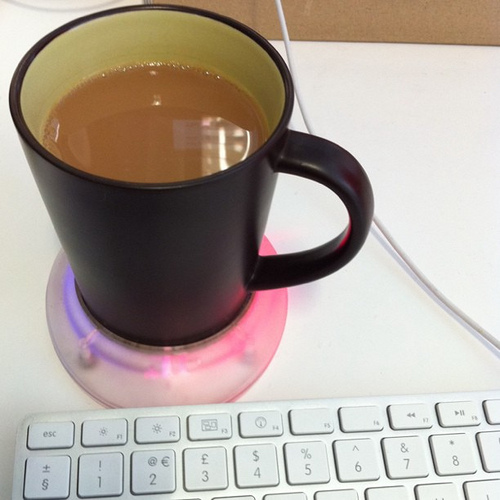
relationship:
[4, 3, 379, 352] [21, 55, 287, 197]
cup of coffee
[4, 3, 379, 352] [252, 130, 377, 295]
cup has handle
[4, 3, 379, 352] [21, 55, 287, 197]
cup filled with coffee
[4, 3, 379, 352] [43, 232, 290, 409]
cup in cupholder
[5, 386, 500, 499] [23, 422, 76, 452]
keyboard has escape key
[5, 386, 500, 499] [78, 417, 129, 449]
keyboard has f1 key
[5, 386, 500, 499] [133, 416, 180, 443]
keyboard has f2 key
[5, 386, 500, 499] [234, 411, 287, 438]
keyboard has f4 key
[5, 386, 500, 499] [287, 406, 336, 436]
keyboard has f5 key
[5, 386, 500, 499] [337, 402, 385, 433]
keyboard has f6 key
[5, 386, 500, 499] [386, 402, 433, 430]
keyboard has f7 key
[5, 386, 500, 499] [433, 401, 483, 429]
keyboard has f8 key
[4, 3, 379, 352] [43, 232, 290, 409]
cup on cupholder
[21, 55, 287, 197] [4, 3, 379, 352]
coffee inside cup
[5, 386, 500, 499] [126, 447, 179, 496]
keyboard has #2 key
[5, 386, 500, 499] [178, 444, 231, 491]
keyboard has #3 key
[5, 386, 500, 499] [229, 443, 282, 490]
keyboard has #4 key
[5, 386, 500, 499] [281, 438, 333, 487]
keyboard has #5 key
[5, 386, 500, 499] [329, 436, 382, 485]
keyboard has #6 key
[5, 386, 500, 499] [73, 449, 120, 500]
keyboard has #1 key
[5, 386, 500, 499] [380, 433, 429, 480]
keyboard has #7 key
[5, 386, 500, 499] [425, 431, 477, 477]
keyboard has #8 key